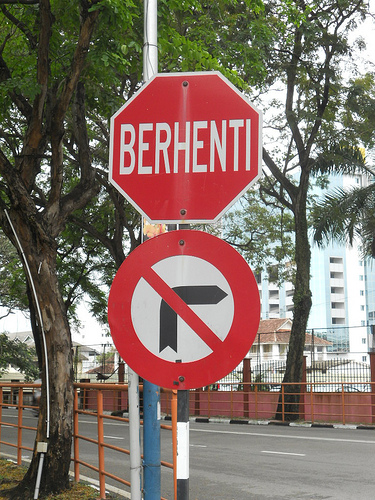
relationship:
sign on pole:
[107, 227, 260, 391] [137, 1, 162, 466]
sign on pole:
[105, 68, 263, 225] [137, 1, 162, 466]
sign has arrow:
[107, 227, 260, 391] [156, 284, 229, 352]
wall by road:
[82, 384, 373, 424] [2, 409, 374, 498]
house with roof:
[236, 318, 333, 390] [253, 316, 334, 349]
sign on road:
[107, 227, 260, 391] [2, 409, 374, 498]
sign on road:
[105, 68, 263, 225] [2, 409, 374, 498]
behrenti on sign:
[118, 118, 254, 178] [105, 68, 263, 225]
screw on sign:
[182, 77, 193, 91] [105, 68, 263, 225]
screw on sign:
[177, 236, 185, 247] [107, 227, 260, 391]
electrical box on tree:
[33, 436, 51, 457] [3, 2, 286, 499]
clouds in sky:
[0, 1, 375, 355] [0, 1, 373, 352]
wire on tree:
[2, 208, 55, 442] [3, 2, 286, 499]